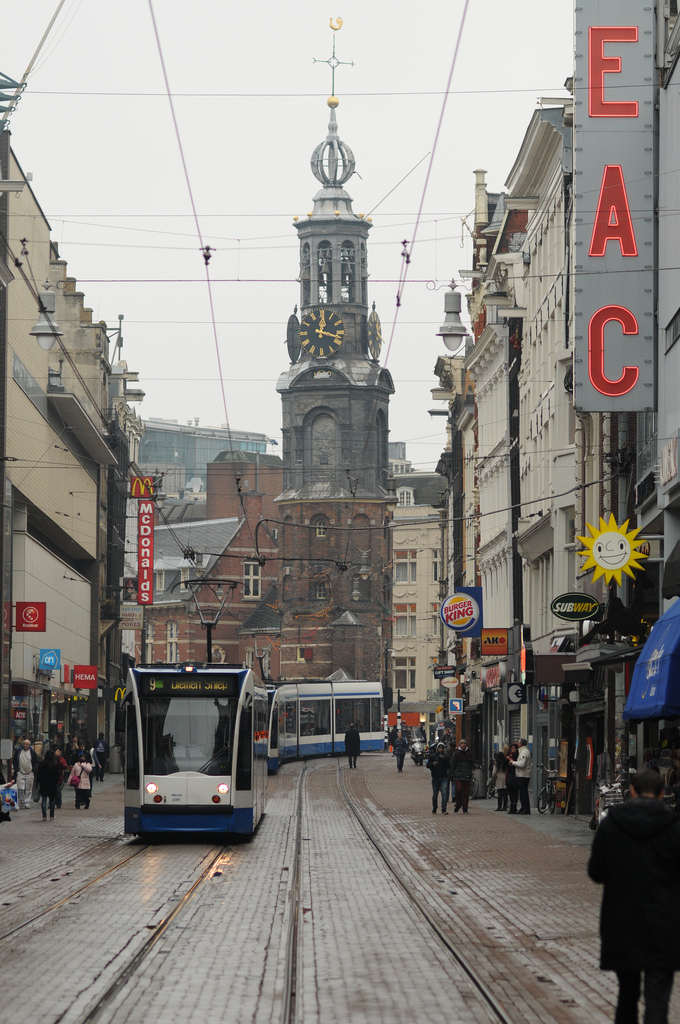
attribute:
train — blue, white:
[116, 671, 261, 834]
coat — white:
[514, 746, 533, 781]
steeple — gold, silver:
[287, 19, 377, 218]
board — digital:
[136, 672, 238, 696]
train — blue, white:
[109, 647, 387, 846]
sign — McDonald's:
[126, 474, 164, 611]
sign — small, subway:
[540, 577, 605, 631]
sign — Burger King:
[439, 587, 489, 642]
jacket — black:
[586, 799, 651, 984]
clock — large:
[296, 310, 355, 360]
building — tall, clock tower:
[276, 58, 395, 506]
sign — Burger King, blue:
[428, 587, 492, 642]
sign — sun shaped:
[581, 511, 649, 587]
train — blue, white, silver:
[125, 663, 387, 837]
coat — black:
[616, 809, 659, 846]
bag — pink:
[68, 770, 81, 787]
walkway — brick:
[443, 832, 575, 924]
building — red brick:
[219, 454, 401, 666]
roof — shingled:
[179, 521, 227, 555]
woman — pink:
[68, 754, 102, 804]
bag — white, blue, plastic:
[6, 783, 22, 807]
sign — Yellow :
[575, 516, 647, 590]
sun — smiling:
[579, 511, 645, 579]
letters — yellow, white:
[551, 599, 604, 613]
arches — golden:
[130, 478, 147, 497]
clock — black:
[300, 311, 350, 360]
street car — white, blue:
[115, 657, 290, 832]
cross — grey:
[303, 20, 357, 94]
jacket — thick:
[416, 747, 458, 776]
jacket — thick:
[446, 749, 478, 798]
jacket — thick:
[505, 749, 532, 778]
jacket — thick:
[580, 809, 676, 959]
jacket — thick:
[28, 757, 65, 801]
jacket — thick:
[70, 762, 102, 791]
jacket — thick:
[384, 732, 408, 754]